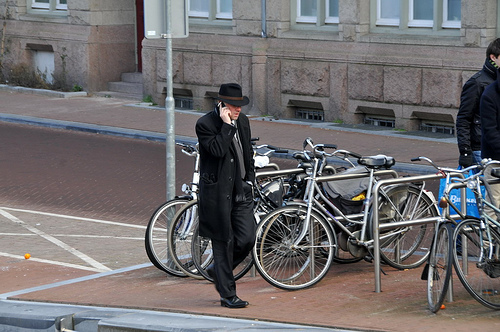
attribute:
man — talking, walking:
[190, 78, 266, 315]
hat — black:
[208, 81, 252, 109]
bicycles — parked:
[406, 149, 492, 315]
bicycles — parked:
[444, 163, 500, 316]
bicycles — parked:
[249, 132, 443, 290]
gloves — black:
[196, 170, 217, 188]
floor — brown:
[1, 202, 497, 331]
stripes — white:
[3, 206, 205, 242]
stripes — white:
[1, 209, 113, 273]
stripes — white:
[0, 235, 199, 239]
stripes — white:
[1, 251, 98, 274]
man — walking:
[450, 34, 500, 259]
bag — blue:
[429, 149, 497, 233]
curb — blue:
[1, 110, 469, 186]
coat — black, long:
[190, 107, 259, 245]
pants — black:
[206, 183, 261, 299]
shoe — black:
[220, 293, 253, 313]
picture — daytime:
[1, 1, 500, 331]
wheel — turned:
[425, 220, 455, 316]